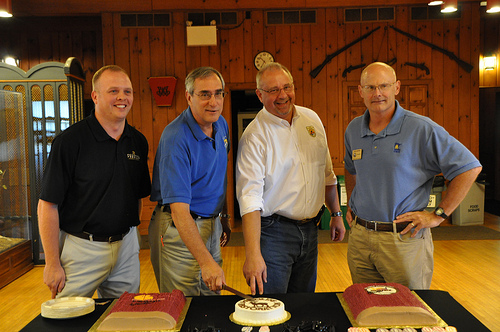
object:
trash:
[313, 155, 365, 250]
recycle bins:
[319, 160, 461, 253]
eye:
[99, 79, 123, 101]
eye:
[119, 82, 134, 97]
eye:
[208, 85, 231, 117]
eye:
[265, 82, 289, 109]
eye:
[279, 77, 302, 100]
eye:
[365, 73, 376, 94]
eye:
[372, 77, 393, 107]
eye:
[113, 87, 137, 108]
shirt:
[156, 110, 237, 210]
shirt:
[317, 95, 469, 248]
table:
[179, 294, 319, 329]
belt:
[333, 202, 412, 242]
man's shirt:
[333, 104, 473, 280]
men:
[62, 63, 420, 152]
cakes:
[110, 283, 450, 327]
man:
[61, 47, 160, 171]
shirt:
[53, 122, 172, 244]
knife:
[218, 281, 253, 302]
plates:
[36, 294, 96, 322]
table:
[18, 289, 489, 330]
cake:
[229, 293, 292, 326]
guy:
[235, 62, 345, 295]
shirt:
[232, 102, 339, 222]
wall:
[81, 0, 479, 230]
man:
[344, 58, 482, 292]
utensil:
[220, 278, 249, 306]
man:
[164, 64, 229, 303]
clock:
[254, 44, 278, 70]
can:
[452, 182, 483, 228]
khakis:
[349, 210, 438, 290]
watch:
[433, 205, 453, 225]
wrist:
[412, 189, 458, 232]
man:
[240, 61, 337, 297]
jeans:
[256, 209, 319, 292]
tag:
[349, 149, 363, 162]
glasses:
[194, 89, 227, 101]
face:
[185, 64, 225, 122]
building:
[0, 0, 497, 329]